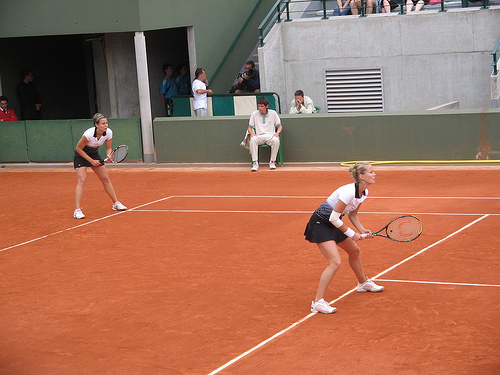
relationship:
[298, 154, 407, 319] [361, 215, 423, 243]
blonde woman holding racket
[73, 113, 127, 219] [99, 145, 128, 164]
person holding racket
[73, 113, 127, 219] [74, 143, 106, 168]
person wearing skirt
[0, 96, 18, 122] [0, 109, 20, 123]
man wearing coat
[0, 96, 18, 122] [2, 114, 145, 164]
man behind wall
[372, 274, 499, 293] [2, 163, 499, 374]
white line on clay court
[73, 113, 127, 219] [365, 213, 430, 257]
person holding racket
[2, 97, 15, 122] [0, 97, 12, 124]
man wearing red jacket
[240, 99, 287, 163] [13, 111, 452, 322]
linesman at tennis match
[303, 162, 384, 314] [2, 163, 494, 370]
person on clay court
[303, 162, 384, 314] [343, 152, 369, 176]
person has hair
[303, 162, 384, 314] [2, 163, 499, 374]
person on clay court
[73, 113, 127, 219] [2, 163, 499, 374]
person on clay court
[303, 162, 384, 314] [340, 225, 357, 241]
person has wristband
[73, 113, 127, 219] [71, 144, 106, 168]
person wears skirt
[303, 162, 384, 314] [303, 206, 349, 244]
person wears skirt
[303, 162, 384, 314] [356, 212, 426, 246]
person holds tennis racket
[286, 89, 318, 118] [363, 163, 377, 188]
man holds face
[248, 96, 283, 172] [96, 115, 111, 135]
linesman holds face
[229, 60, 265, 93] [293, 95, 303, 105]
man holds face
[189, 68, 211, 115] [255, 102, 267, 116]
man holds face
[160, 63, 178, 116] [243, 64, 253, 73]
man holds face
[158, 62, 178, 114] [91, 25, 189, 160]
man on wall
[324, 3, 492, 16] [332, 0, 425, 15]
people has legs